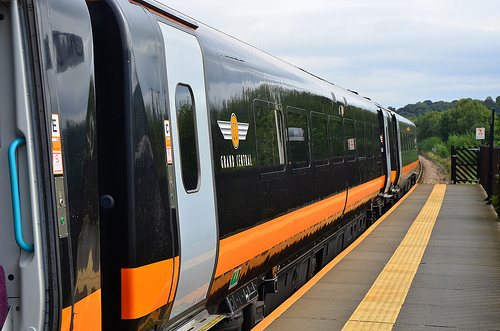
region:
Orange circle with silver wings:
[212, 110, 257, 152]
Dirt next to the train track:
[415, 145, 450, 185]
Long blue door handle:
[7, 138, 44, 258]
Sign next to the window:
[162, 122, 179, 164]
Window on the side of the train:
[272, 108, 289, 168]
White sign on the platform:
[472, 123, 486, 139]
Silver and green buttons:
[52, 178, 73, 237]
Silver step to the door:
[164, 300, 232, 329]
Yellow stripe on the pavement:
[337, 170, 452, 329]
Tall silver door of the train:
[155, 12, 235, 325]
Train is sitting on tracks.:
[0, 0, 427, 328]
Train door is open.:
[0, 0, 61, 330]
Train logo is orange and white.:
[212, 110, 257, 172]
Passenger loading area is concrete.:
[242, 181, 499, 329]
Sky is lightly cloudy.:
[155, 0, 492, 110]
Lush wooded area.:
[405, 95, 497, 160]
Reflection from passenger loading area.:
[170, 250, 220, 315]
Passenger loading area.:
[245, 180, 495, 327]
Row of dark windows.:
[250, 95, 420, 175]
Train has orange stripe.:
[0, 0, 450, 330]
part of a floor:
[436, 244, 467, 284]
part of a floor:
[388, 216, 418, 262]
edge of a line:
[391, 287, 407, 321]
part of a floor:
[439, 225, 475, 275]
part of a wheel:
[274, 280, 291, 302]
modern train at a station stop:
[46, 5, 471, 316]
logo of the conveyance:
[212, 105, 252, 150]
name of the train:
[215, 147, 255, 172]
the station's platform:
[366, 220, 482, 326]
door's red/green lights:
[50, 175, 70, 240]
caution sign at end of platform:
[465, 120, 485, 145]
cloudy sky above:
[340, 6, 485, 71]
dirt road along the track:
[416, 150, 441, 180]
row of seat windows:
[255, 97, 381, 168]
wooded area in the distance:
[417, 95, 472, 141]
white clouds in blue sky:
[252, 11, 301, 42]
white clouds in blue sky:
[320, 15, 345, 51]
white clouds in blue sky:
[366, 35, 400, 81]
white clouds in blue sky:
[396, 30, 431, 95]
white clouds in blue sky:
[435, 22, 478, 83]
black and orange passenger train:
[85, 5, 377, 260]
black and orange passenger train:
[318, 90, 413, 200]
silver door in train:
[151, 20, 231, 308]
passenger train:
[205, 47, 352, 242]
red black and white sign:
[471, 115, 490, 150]